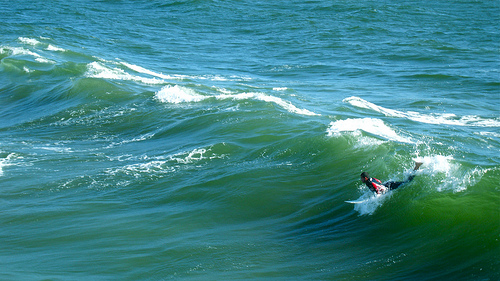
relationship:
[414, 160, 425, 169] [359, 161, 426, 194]
foot of surfer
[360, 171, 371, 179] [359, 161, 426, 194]
hair of surfer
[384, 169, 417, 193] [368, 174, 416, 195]
pants of wet suit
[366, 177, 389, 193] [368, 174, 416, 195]
shirt of wet suit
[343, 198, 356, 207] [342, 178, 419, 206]
tip of surfboard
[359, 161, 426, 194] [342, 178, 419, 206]
surfer laying on top of surfboard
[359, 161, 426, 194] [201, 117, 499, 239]
surfer riding wave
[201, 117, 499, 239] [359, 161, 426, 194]
wave behind surfer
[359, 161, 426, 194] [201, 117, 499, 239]
male surfer ready to ride a wave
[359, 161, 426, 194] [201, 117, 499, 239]
surfer ready to ride a wave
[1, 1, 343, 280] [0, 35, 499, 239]
ocean water with wave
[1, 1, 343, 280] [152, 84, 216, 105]
ocean water with foam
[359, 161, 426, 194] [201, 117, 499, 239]
surfer riding a wave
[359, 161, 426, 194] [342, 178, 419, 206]
surfer on top of a surfboard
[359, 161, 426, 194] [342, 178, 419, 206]
surfer on top of a boar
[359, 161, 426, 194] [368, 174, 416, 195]
surfer wearing a wetsuit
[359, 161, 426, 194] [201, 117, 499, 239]
person riding a wave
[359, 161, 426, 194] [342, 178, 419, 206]
person on top of a white surfboard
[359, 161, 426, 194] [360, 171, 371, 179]
person has hair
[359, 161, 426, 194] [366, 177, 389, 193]
person has on a top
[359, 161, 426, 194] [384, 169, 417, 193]
person wearing pants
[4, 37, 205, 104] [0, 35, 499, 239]
white caps on top of wave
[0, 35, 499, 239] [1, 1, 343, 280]
wave on top of water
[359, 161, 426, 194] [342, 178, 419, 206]
person has a surfboard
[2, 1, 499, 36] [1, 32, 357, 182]
water behind wave